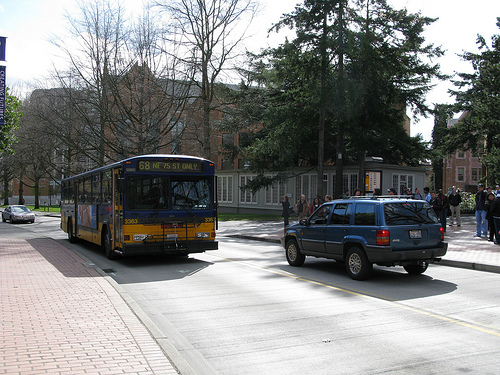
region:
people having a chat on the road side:
[286, 154, 496, 199]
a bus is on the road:
[64, 176, 234, 291]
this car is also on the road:
[283, 206, 437, 281]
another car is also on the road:
[10, 207, 36, 242]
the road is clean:
[13, 226, 330, 371]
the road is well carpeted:
[182, 265, 496, 372]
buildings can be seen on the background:
[233, 141, 391, 207]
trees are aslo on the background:
[28, 134, 75, 153]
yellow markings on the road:
[236, 250, 443, 372]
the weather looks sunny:
[3, 9, 428, 359]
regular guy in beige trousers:
[444, 182, 464, 229]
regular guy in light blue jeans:
[470, 180, 490, 242]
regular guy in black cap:
[474, 181, 484, 192]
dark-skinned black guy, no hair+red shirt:
[433, 185, 450, 231]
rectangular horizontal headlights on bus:
[130, 227, 211, 244]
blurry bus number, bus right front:
[121, 215, 141, 226]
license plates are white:
[160, 227, 423, 246]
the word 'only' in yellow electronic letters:
[178, 160, 198, 170]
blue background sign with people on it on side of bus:
[71, 200, 103, 234]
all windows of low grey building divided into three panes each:
[210, 169, 418, 206]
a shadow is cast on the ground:
[276, 251, 421, 318]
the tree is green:
[230, 57, 347, 156]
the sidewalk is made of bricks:
[47, 282, 117, 353]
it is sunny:
[8, 55, 414, 372]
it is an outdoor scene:
[9, 46, 411, 373]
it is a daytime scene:
[14, 51, 452, 366]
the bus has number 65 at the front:
[83, 143, 246, 275]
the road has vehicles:
[13, 58, 483, 370]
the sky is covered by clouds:
[23, 53, 41, 68]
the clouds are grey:
[28, 32, 55, 72]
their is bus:
[129, 152, 231, 283]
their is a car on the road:
[292, 206, 432, 284]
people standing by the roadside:
[397, 187, 499, 246]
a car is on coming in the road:
[16, 167, 74, 265]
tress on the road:
[309, 83, 449, 188]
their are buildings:
[162, 86, 247, 148]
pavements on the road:
[60, 268, 125, 360]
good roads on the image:
[43, 233, 461, 373]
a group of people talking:
[304, 155, 443, 196]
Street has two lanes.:
[5, 154, 498, 371]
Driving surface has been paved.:
[6, 197, 494, 373]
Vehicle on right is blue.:
[268, 180, 449, 290]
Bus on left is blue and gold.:
[50, 145, 223, 267]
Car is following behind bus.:
[0, 189, 46, 233]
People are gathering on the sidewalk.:
[270, 172, 498, 257]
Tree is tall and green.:
[236, 29, 434, 231]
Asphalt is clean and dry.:
[0, 203, 497, 372]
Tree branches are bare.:
[38, 27, 228, 209]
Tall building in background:
[23, 60, 263, 214]